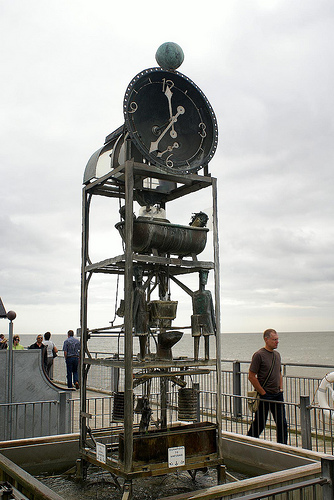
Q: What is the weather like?
A: It is overcast.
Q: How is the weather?
A: It is overcast.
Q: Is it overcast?
A: Yes, it is overcast.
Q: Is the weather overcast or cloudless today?
A: It is overcast.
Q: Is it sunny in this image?
A: No, it is overcast.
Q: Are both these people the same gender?
A: No, they are both male and female.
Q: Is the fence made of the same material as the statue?
A: Yes, both the fence and the statue are made of metal.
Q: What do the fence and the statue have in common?
A: The material, both the fence and the statue are metallic.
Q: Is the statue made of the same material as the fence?
A: Yes, both the statue and the fence are made of metal.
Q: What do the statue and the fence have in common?
A: The material, both the statue and the fence are metallic.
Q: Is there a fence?
A: Yes, there is a fence.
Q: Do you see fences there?
A: Yes, there is a fence.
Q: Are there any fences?
A: Yes, there is a fence.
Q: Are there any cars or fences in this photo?
A: Yes, there is a fence.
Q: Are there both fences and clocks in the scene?
A: Yes, there are both a fence and a clock.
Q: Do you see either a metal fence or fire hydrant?
A: Yes, there is a metal fence.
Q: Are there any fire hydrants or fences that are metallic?
A: Yes, the fence is metallic.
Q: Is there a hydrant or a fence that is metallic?
A: Yes, the fence is metallic.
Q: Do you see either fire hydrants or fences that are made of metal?
A: Yes, the fence is made of metal.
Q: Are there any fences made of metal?
A: Yes, there is a fence that is made of metal.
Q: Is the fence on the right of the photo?
A: Yes, the fence is on the right of the image.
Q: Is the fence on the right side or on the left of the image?
A: The fence is on the right of the image.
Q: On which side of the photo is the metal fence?
A: The fence is on the right of the image.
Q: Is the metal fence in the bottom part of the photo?
A: Yes, the fence is in the bottom of the image.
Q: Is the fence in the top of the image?
A: No, the fence is in the bottom of the image.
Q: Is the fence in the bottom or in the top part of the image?
A: The fence is in the bottom of the image.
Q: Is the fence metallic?
A: Yes, the fence is metallic.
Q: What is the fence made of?
A: The fence is made of metal.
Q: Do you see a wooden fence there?
A: No, there is a fence but it is metallic.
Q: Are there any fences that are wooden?
A: No, there is a fence but it is metallic.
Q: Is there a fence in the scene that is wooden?
A: No, there is a fence but it is metallic.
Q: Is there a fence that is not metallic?
A: No, there is a fence but it is metallic.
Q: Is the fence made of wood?
A: No, the fence is made of metal.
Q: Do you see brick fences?
A: No, there is a fence but it is made of metal.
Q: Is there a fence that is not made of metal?
A: No, there is a fence but it is made of metal.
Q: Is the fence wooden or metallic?
A: The fence is metallic.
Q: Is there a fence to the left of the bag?
A: Yes, there is a fence to the left of the bag.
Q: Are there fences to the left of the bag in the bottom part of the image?
A: Yes, there is a fence to the left of the bag.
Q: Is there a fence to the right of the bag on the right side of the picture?
A: No, the fence is to the left of the bag.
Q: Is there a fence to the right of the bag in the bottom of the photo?
A: No, the fence is to the left of the bag.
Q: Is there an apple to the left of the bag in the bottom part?
A: No, there is a fence to the left of the bag.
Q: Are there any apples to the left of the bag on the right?
A: No, there is a fence to the left of the bag.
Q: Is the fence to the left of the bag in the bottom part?
A: Yes, the fence is to the left of the bag.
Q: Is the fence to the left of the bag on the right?
A: Yes, the fence is to the left of the bag.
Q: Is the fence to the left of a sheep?
A: No, the fence is to the left of the bag.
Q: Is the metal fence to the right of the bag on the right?
A: No, the fence is to the left of the bag.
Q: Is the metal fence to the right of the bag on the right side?
A: No, the fence is to the left of the bag.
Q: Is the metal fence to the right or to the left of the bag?
A: The fence is to the left of the bag.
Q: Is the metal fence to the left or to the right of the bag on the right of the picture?
A: The fence is to the left of the bag.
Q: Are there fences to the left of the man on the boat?
A: Yes, there is a fence to the left of the man.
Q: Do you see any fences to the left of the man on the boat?
A: Yes, there is a fence to the left of the man.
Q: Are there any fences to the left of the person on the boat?
A: Yes, there is a fence to the left of the man.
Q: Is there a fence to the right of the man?
A: No, the fence is to the left of the man.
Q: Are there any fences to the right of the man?
A: No, the fence is to the left of the man.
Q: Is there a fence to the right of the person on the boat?
A: No, the fence is to the left of the man.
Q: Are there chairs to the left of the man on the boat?
A: No, there is a fence to the left of the man.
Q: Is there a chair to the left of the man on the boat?
A: No, there is a fence to the left of the man.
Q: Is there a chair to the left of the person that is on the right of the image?
A: No, there is a fence to the left of the man.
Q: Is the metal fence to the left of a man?
A: Yes, the fence is to the left of a man.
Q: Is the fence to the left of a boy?
A: No, the fence is to the left of a man.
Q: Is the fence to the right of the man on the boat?
A: No, the fence is to the left of the man.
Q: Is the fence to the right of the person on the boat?
A: No, the fence is to the left of the man.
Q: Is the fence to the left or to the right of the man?
A: The fence is to the left of the man.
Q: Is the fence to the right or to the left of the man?
A: The fence is to the left of the man.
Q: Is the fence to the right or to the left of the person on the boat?
A: The fence is to the left of the man.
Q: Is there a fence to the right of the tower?
A: Yes, there is a fence to the right of the tower.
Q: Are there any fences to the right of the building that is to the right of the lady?
A: Yes, there is a fence to the right of the tower.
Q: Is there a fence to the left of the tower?
A: No, the fence is to the right of the tower.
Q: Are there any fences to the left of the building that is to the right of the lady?
A: No, the fence is to the right of the tower.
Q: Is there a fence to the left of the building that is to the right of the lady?
A: No, the fence is to the right of the tower.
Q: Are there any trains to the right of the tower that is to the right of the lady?
A: No, there is a fence to the right of the tower.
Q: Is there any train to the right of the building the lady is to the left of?
A: No, there is a fence to the right of the tower.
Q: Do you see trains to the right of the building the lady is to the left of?
A: No, there is a fence to the right of the tower.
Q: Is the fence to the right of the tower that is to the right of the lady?
A: Yes, the fence is to the right of the tower.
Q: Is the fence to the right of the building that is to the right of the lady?
A: Yes, the fence is to the right of the tower.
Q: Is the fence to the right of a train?
A: No, the fence is to the right of the tower.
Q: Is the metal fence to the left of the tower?
A: No, the fence is to the right of the tower.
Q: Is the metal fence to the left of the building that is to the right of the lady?
A: No, the fence is to the right of the tower.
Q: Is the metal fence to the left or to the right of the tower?
A: The fence is to the right of the tower.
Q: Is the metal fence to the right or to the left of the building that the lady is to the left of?
A: The fence is to the right of the tower.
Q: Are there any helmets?
A: No, there are no helmets.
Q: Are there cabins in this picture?
A: No, there are no cabins.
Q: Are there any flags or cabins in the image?
A: No, there are no cabins or flags.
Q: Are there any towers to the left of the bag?
A: Yes, there is a tower to the left of the bag.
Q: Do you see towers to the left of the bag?
A: Yes, there is a tower to the left of the bag.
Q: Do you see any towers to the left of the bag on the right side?
A: Yes, there is a tower to the left of the bag.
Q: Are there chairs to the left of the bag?
A: No, there is a tower to the left of the bag.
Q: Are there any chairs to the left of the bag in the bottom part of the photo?
A: No, there is a tower to the left of the bag.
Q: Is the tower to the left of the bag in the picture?
A: Yes, the tower is to the left of the bag.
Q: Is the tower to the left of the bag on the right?
A: Yes, the tower is to the left of the bag.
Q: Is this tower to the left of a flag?
A: No, the tower is to the left of the bag.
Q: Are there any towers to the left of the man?
A: Yes, there is a tower to the left of the man.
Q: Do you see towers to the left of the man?
A: Yes, there is a tower to the left of the man.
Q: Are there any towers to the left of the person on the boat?
A: Yes, there is a tower to the left of the man.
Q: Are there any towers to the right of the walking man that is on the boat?
A: No, the tower is to the left of the man.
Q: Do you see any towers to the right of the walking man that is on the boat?
A: No, the tower is to the left of the man.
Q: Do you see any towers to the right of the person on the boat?
A: No, the tower is to the left of the man.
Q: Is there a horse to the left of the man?
A: No, there is a tower to the left of the man.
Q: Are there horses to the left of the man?
A: No, there is a tower to the left of the man.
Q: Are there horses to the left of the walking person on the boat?
A: No, there is a tower to the left of the man.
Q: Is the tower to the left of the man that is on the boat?
A: Yes, the tower is to the left of the man.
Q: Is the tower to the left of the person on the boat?
A: Yes, the tower is to the left of the man.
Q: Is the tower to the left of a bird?
A: No, the tower is to the left of the man.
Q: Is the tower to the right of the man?
A: No, the tower is to the left of the man.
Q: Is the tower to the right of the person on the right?
A: No, the tower is to the left of the man.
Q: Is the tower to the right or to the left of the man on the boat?
A: The tower is to the left of the man.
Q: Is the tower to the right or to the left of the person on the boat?
A: The tower is to the left of the man.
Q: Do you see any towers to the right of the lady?
A: Yes, there is a tower to the right of the lady.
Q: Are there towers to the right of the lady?
A: Yes, there is a tower to the right of the lady.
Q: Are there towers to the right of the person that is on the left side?
A: Yes, there is a tower to the right of the lady.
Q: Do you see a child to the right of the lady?
A: No, there is a tower to the right of the lady.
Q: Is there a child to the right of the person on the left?
A: No, there is a tower to the right of the lady.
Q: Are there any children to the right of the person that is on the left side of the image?
A: No, there is a tower to the right of the lady.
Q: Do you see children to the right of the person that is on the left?
A: No, there is a tower to the right of the lady.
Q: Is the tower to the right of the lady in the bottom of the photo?
A: Yes, the tower is to the right of the lady.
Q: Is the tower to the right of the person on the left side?
A: Yes, the tower is to the right of the lady.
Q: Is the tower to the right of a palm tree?
A: No, the tower is to the right of the lady.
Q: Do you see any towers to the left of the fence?
A: Yes, there is a tower to the left of the fence.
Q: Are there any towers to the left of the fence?
A: Yes, there is a tower to the left of the fence.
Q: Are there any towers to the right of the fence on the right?
A: No, the tower is to the left of the fence.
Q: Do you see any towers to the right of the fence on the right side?
A: No, the tower is to the left of the fence.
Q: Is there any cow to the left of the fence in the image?
A: No, there is a tower to the left of the fence.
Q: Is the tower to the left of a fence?
A: Yes, the tower is to the left of a fence.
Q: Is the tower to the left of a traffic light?
A: No, the tower is to the left of a fence.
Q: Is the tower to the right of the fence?
A: No, the tower is to the left of the fence.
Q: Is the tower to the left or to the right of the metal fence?
A: The tower is to the left of the fence.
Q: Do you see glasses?
A: No, there are no glasses.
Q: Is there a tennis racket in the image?
A: No, there are no rackets.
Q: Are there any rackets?
A: No, there are no rackets.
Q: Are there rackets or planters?
A: No, there are no rackets or planters.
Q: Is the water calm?
A: Yes, the water is calm.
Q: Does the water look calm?
A: Yes, the water is calm.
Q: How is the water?
A: The water is calm.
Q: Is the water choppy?
A: No, the water is calm.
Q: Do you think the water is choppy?
A: No, the water is calm.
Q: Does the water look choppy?
A: No, the water is calm.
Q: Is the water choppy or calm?
A: The water is calm.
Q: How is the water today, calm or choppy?
A: The water is calm.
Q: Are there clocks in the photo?
A: Yes, there is a clock.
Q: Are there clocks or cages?
A: Yes, there is a clock.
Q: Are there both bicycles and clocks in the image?
A: No, there is a clock but no bicycles.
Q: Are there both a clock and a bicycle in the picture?
A: No, there is a clock but no bicycles.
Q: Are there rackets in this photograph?
A: No, there are no rackets.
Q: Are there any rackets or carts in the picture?
A: No, there are no rackets or carts.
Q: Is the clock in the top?
A: Yes, the clock is in the top of the image.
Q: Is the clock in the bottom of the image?
A: No, the clock is in the top of the image.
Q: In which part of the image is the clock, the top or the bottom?
A: The clock is in the top of the image.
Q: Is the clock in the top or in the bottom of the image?
A: The clock is in the top of the image.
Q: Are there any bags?
A: Yes, there is a bag.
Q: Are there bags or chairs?
A: Yes, there is a bag.